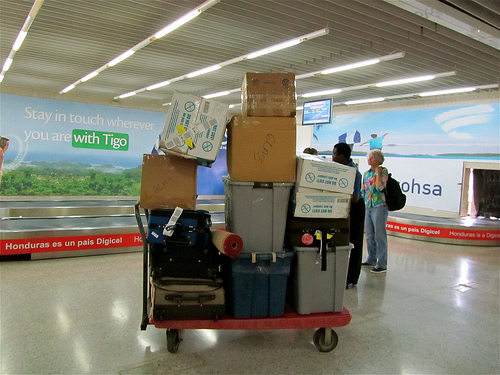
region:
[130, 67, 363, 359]
Boxes and crates are sitting on a cart.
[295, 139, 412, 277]
Three people are behind the cart.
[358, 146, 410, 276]
A person is carrying a backpack.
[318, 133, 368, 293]
A black man is behind the cart.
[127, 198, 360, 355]
The cart's color is red and black.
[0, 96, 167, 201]
An advertisement for Tigo is in the background.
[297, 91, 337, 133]
A monitor is attached to a wall.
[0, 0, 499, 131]
Six florescent lights are attached to the ceiling.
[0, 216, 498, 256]
Writing in Spanish is on two platforms.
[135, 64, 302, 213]
Three boxes are brown.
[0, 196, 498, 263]
Luggage belt.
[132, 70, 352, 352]
Cart full of luggage and boxes.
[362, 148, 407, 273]
Woman in floral shirt and jeans.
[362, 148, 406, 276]
Woman with a black backpack.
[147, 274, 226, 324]
Brown and beige suitcase.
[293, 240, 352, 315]
Grey plastic container.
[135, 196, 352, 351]
Metal dolly with red base.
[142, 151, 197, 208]
Cardboard box marked "Glass".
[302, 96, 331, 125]
Screen.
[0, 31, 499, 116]
Ceiling with floresent lighting.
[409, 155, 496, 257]
baggage claim belt in an airport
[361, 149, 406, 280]
woman wearing jeans with a black backpack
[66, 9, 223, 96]
fluorescent overhead lighting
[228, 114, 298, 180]
cardboard box with "glass" written on the side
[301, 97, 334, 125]
a television screen mounted near the ceiling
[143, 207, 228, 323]
stack of three suitcases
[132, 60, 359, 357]
rolling cart in an airport baggage claim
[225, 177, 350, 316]
plastic tote container bins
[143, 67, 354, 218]
cardboard boxes piled on an airport cart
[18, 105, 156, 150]
An advertisement painted on the wall about Tigo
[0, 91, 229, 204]
wall has painted mural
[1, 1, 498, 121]
florescent lights on ceiling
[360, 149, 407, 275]
the woman with rey hair has a backpack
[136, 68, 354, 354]
cardboard boxes on the cart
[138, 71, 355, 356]
plastic bins on the cart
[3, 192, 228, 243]
the conveyer belts have no luggage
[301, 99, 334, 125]
flat screen TV in corner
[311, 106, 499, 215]
the wall has a painted mural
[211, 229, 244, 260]
cart has a brown paper roll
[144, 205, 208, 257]
blue suitcase on cart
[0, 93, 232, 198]
Wall painted to look like a sky with words on it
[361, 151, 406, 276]
Woman with a black backpack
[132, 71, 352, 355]
Boxes and luggage on a dolly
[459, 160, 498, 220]
opening for luggage to come through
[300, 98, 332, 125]
screen hanging from ceiling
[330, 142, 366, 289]
man with dark pants and blue polo shirt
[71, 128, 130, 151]
Lettering that says with tigo in a green box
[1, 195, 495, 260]
luggage conveyor belt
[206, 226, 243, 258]
rolled tan and red mat on top of trolley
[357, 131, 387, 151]
painting of boy pointing at clouds